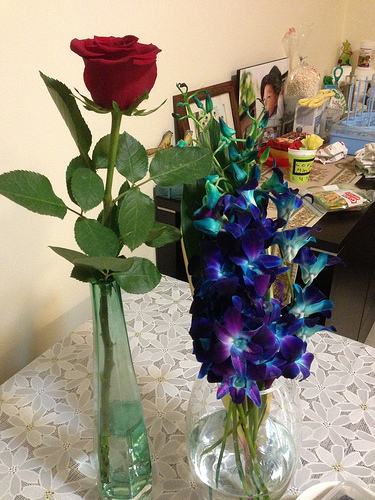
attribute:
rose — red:
[61, 21, 170, 128]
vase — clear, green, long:
[78, 265, 155, 495]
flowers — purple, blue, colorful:
[174, 81, 338, 398]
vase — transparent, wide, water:
[178, 382, 303, 499]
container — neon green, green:
[287, 141, 320, 185]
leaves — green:
[2, 104, 211, 294]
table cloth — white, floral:
[0, 274, 372, 499]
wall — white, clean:
[6, 5, 374, 37]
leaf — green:
[37, 68, 98, 153]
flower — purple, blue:
[194, 301, 289, 381]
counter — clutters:
[143, 110, 374, 248]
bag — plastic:
[280, 26, 321, 92]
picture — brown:
[171, 81, 240, 148]